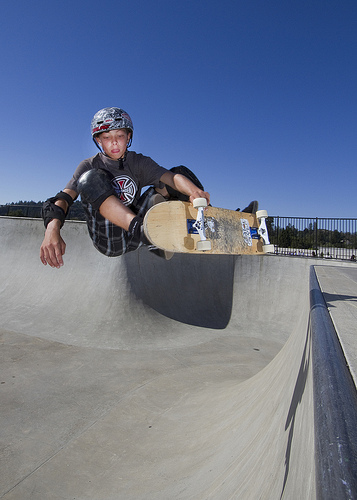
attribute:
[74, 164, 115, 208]
knee pad — black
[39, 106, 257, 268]
boy — focused, skateboarding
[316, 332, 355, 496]
bar — black, steel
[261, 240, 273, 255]
wheel — white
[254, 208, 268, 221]
wheel — white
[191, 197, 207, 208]
wheel — white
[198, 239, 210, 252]
wheel — white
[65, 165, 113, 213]
pad — knee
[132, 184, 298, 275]
skateboard — wooden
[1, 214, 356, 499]
ramp — concrete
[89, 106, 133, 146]
helmet — blue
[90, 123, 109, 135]
letters — red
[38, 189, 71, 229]
elbow pad — black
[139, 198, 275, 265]
skateboard — sideways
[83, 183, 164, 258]
shorts — plaid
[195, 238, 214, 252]
wheel — white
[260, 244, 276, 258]
wheel — white